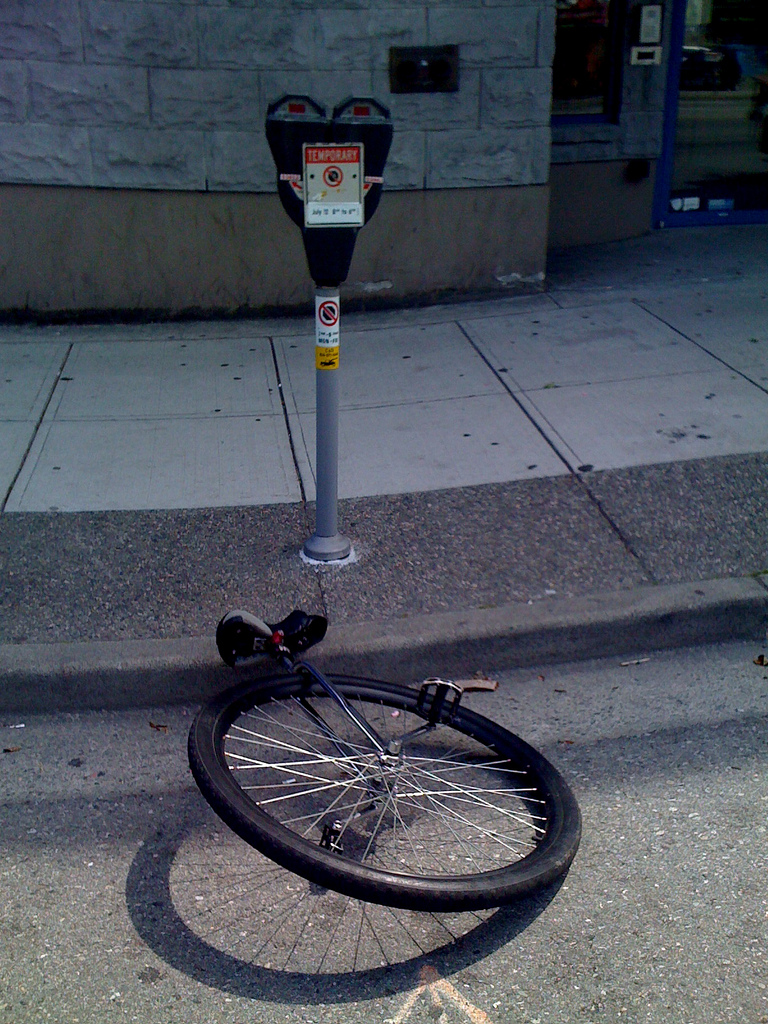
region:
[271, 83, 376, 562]
parking meter on the sidewalk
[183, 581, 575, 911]
unicycle laying on the street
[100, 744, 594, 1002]
shadow of the unicycle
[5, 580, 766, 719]
curb of the sidewalk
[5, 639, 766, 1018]
street by the sidewalk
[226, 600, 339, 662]
seat on the unicycle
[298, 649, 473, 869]
pedals on the unicycle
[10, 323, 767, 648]
sidewalk the parking meter is on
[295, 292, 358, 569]
gray pole the parking meter is on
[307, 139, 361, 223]
sign on the black parking meter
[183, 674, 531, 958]
Black tire on unicycle.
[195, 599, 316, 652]
Dark seat on bike.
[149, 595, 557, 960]
Unicycle is leaning on the side of the curb.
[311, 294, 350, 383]
Sticker stuck to silver pole.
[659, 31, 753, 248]
Door has blue frame.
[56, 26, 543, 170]
Stone building in background.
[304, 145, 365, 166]
White wording on parking meter.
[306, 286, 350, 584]
Silver pole connected to parking meter.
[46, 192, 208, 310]
brick that is light brown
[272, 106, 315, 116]
a bunch of red numbers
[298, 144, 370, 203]
a sign that red and white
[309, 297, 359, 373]
a sign that is white and yellow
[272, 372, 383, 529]
a pole that is grey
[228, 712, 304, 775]
the spokes of a unicycle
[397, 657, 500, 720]
the pedal of a unicycle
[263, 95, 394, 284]
A parking meter with a sign on it.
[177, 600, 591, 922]
A unicycle lying on the black top.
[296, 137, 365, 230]
A out of order sign.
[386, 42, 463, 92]
A black plate on a building.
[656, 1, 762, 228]
A blue glass door on a building.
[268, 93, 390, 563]
A black and gray parking meter.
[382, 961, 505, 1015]
A orange arrow on the black top.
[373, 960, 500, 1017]
A arrow pointing toward the Unicycle.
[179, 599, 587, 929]
A one wheel bike cycle .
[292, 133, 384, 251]
red and white sign on the meter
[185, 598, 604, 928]
unicycle on the ground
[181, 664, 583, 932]
tire of the unicycle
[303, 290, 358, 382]
sticker on the meter's post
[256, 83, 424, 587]
parking meter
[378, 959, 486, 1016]
arrow painted on the road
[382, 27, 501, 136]
black box on the brick wall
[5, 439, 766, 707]
darker edge of the sidewalk and curb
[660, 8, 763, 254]
blue door frame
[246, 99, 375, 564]
A parking meter on the side of the road.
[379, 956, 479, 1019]
A arrow spray painted on the road.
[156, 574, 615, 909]
A unicycle laying on the side of the road.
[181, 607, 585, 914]
A unicycle is parked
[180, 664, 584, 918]
Round black tire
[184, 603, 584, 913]
Unicycle has pedals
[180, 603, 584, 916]
Unicycle has worn seat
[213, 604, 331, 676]
Black worn seat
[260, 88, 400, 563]
Black parking meter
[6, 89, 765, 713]
Parking meter on the sidewalk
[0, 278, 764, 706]
Empty side walk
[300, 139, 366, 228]
Rectangular sign on the parking meter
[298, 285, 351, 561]
Sticker on the post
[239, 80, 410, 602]
a double parking meter on a sidewalk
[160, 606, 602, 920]
a unicycle on its side by a roadway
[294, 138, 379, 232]
a temporary parking sign on a parking meter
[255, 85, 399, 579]
parking meter on the sidewalk